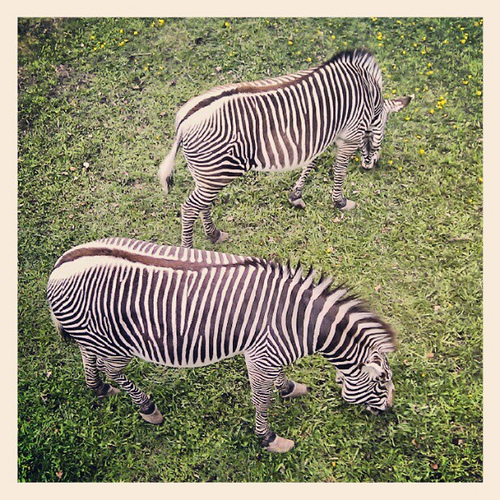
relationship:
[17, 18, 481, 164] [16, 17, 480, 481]
flower in field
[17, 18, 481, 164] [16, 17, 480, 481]
flower on field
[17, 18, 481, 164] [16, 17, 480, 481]
flower is in field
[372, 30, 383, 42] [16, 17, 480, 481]
flower is in field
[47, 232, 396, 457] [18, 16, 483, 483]
zebra is in grass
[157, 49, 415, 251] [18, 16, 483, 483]
zebra is in grass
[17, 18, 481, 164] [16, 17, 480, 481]
flower are in field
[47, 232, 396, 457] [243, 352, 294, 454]
zebra stands on leg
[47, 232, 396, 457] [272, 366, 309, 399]
zebra stands on leg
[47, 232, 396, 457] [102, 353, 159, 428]
zebra stands on leg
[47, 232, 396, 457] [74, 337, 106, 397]
zebra stands on leg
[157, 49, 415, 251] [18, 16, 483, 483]
zebra eating grass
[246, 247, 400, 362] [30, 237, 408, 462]
mane on zebra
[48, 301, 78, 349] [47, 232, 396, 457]
tail on zebra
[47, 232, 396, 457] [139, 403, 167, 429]
zebra has hoof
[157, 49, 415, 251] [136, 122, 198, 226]
zebra has tail